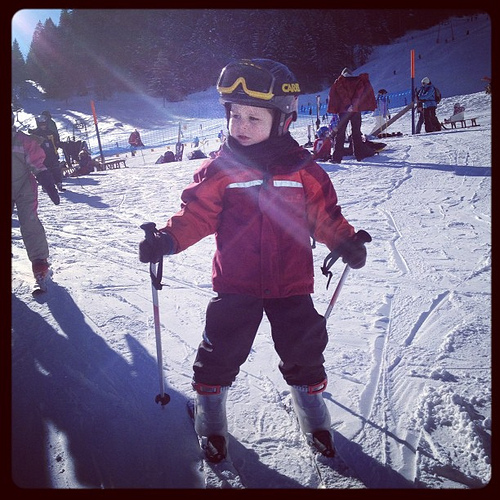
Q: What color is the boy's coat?
A: Red.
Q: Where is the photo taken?
A: In the mountains.